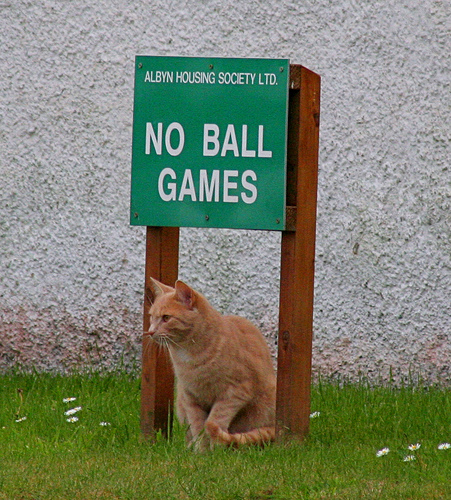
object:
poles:
[138, 227, 181, 448]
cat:
[147, 276, 275, 450]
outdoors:
[2, 2, 447, 497]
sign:
[128, 54, 290, 230]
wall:
[0, 2, 448, 381]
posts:
[143, 68, 277, 207]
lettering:
[157, 167, 257, 204]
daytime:
[0, 0, 450, 498]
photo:
[0, 0, 451, 500]